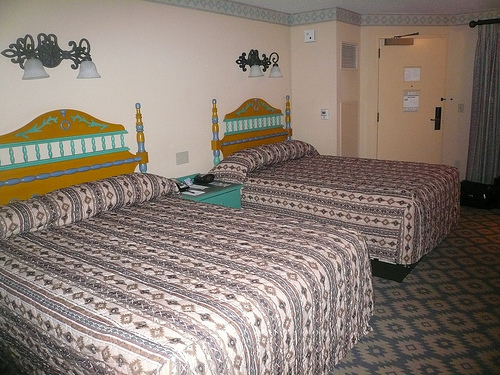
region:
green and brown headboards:
[0, 105, 143, 208]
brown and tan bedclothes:
[0, 199, 350, 374]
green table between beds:
[176, 166, 231, 212]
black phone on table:
[190, 162, 212, 189]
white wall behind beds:
[142, 82, 206, 140]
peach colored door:
[375, 44, 442, 165]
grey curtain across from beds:
[465, 21, 499, 179]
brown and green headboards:
[2, 107, 139, 202]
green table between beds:
[154, 164, 244, 216]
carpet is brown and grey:
[348, 228, 488, 372]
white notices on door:
[392, 58, 436, 125]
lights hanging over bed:
[7, 48, 102, 82]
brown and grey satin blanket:
[21, 183, 355, 373]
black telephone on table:
[175, 163, 223, 197]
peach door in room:
[367, 37, 451, 167]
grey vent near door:
[321, 35, 365, 82]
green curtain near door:
[451, 44, 491, 204]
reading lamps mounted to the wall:
[3, 27, 103, 83]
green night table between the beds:
[176, 169, 250, 208]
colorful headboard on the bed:
[2, 102, 153, 205]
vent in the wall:
[340, 42, 360, 77]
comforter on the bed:
[5, 165, 384, 373]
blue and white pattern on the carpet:
[344, 171, 498, 371]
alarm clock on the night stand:
[190, 171, 219, 187]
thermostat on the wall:
[320, 104, 328, 124]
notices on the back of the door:
[397, 61, 427, 116]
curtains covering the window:
[465, 16, 494, 191]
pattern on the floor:
[393, 334, 421, 356]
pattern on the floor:
[429, 333, 466, 355]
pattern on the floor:
[397, 300, 424, 317]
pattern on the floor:
[429, 297, 446, 313]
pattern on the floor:
[454, 290, 475, 310]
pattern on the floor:
[353, 340, 391, 361]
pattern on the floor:
[448, 358, 475, 371]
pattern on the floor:
[393, 288, 408, 300]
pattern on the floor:
[448, 269, 465, 279]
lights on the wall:
[236, 45, 293, 86]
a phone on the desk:
[172, 178, 187, 186]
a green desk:
[183, 175, 245, 205]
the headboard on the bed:
[9, 105, 183, 188]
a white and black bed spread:
[18, 175, 347, 367]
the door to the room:
[373, 34, 445, 160]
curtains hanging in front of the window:
[466, 38, 498, 184]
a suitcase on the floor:
[458, 180, 496, 204]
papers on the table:
[187, 183, 209, 193]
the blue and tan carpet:
[381, 280, 493, 360]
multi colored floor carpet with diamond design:
[421, 323, 471, 362]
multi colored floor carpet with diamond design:
[373, 310, 420, 350]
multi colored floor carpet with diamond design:
[418, 289, 460, 316]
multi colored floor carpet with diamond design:
[413, 263, 452, 285]